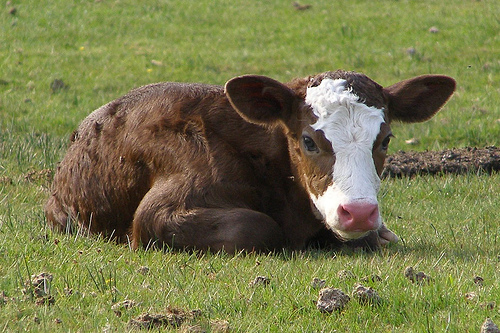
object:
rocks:
[20, 244, 497, 330]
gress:
[6, 254, 490, 328]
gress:
[11, 6, 484, 73]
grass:
[396, 173, 467, 233]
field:
[13, 11, 489, 331]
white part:
[299, 79, 390, 242]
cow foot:
[370, 221, 402, 248]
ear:
[221, 73, 297, 128]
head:
[223, 66, 457, 242]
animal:
[43, 70, 457, 259]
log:
[382, 129, 489, 185]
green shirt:
[334, 196, 389, 235]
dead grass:
[317, 285, 347, 311]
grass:
[21, 12, 491, 322]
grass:
[1, 6, 498, 76]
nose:
[338, 199, 377, 224]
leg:
[130, 182, 289, 254]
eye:
[298, 132, 320, 156]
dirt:
[416, 131, 467, 189]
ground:
[8, 221, 485, 319]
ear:
[385, 73, 455, 124]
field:
[3, 223, 483, 331]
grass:
[6, 158, 484, 323]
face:
[294, 71, 395, 237]